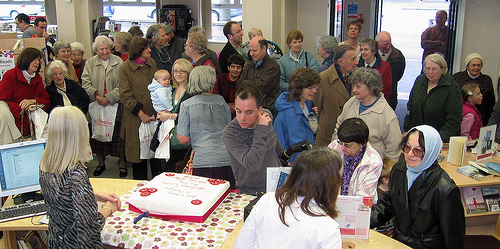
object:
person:
[82, 36, 127, 178]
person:
[176, 65, 237, 190]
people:
[0, 2, 495, 223]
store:
[0, 0, 498, 248]